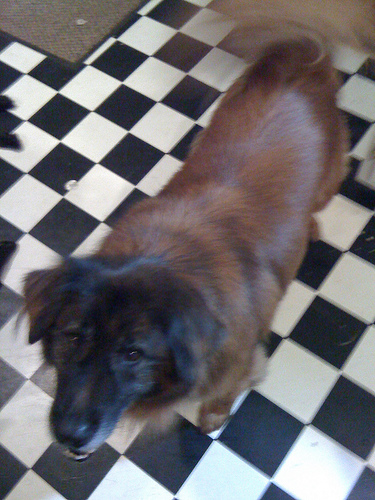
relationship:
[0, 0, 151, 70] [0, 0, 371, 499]
rug on floor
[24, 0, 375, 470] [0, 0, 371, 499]
dog standing on floor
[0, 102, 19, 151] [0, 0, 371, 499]
paws on floor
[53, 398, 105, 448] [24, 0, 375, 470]
nose on dog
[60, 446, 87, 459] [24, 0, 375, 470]
teeth on dog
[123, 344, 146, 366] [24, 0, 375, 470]
eye on dog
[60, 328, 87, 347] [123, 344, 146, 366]
brown eye on eye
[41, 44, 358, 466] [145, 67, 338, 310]
hair on dog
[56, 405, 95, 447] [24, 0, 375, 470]
snout on dog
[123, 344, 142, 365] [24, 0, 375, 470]
eye on dog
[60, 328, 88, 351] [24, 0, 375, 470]
brown eye on dog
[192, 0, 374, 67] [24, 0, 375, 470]
tail on dog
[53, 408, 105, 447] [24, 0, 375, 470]
nose of dog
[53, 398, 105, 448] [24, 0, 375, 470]
nose of dog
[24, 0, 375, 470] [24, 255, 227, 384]
dog has ears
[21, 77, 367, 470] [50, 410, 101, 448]
dog has nose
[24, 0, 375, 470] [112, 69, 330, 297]
dog has back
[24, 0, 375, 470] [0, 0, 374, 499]
dog on black/white floor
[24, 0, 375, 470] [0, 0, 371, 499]
dog on floor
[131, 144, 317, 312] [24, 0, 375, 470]
fur of dog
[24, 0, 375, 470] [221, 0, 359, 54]
dog has tail